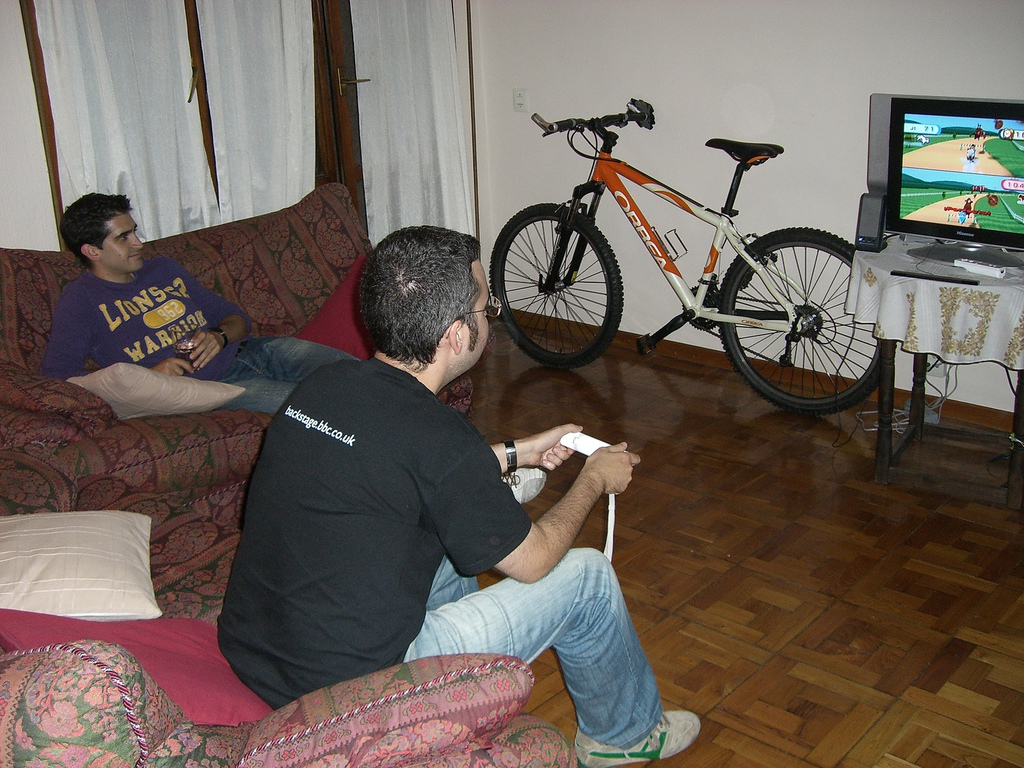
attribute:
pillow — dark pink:
[0, 610, 269, 724]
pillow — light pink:
[2, 509, 158, 624]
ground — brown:
[453, 323, 1022, 766]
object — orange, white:
[477, 105, 882, 420]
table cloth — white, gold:
[841, 244, 1022, 365]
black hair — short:
[345, 225, 495, 368]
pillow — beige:
[63, 352, 238, 420]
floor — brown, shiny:
[442, 317, 1019, 763]